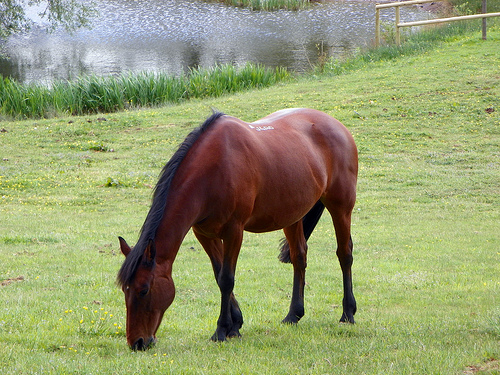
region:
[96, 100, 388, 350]
Roan colored horse grazing on grass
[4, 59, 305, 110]
Tall weeds on the edge of a pond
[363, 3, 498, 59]
Metal railing leading to the water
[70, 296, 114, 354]
Yellow wild flowers on the meadow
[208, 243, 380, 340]
Roan horse has black stocking markings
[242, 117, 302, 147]
White brand on horses back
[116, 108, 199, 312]
Black horses mane blowing in the wind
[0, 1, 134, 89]
Reflection of tree limbs in the water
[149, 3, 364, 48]
Sunlight reflecting off the pond water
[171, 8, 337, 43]
Sunlight reflecting off the water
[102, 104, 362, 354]
dark brown horse hair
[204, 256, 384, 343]
four black horse legs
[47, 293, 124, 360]
yellow flowers on green grass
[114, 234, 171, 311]
black horse hair on the head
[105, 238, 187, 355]
brown horse face with black nose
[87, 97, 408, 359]
horse with head down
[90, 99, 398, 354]
brown horse eating grass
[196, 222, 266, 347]
crossed horse legs on grass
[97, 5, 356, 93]
grass near lake water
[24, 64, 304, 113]
long and tall green grass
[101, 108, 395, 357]
A brown horse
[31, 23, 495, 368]
A field of grass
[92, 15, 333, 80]
The water is calm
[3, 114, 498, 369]
A horse in a field of grass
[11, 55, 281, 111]
tall grass near the water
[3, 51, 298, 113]
tall grass is green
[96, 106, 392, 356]
the horse is standing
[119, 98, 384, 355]
the horse is grazing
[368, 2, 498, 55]
a fence near the water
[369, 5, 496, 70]
the fence is made of wood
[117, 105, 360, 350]
brown horse with black mane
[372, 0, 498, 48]
metal handrail leading to the water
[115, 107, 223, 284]
beautiful black horse mane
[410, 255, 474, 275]
green grass next to the horse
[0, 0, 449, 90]
small body of water behind horse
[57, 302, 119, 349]
yellow dandelions growing in the grass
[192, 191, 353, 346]
horses front and back legs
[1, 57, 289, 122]
tall green weeds growing near water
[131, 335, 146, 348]
brown horse's left snout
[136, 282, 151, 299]
brown horse's left eye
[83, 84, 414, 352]
Horse in the field.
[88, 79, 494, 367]
Horse eating grass.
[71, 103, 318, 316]
Black mane on the brown horse.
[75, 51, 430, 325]
Water behind the horse.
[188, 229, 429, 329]
Four legs on the horse.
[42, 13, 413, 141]
Grass by the water.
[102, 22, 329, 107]
Reflections in the water.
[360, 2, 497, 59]
Railings heading to the water.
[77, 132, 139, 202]
Flowers on the grass.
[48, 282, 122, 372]
Yellow flowers by the horse.